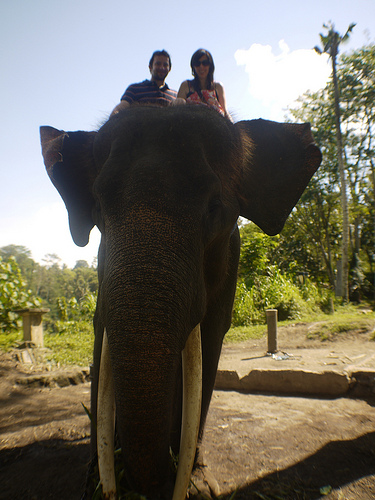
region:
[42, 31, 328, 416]
two people on the back of an elephant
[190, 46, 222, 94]
a woman with long hair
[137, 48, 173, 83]
a man with black hair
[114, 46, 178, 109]
a man wearing a striped shirt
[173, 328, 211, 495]
a long ivory elephant tusk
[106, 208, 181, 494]
the trunk of an elephant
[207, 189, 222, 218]
the eye of an elephant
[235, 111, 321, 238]
the ear of an elephant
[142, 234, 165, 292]
wrinkled skin on an elephant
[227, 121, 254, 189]
hair on an elephant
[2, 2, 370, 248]
blue of daytime sky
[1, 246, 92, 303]
green leaves on trees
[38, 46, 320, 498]
two people on top of elephant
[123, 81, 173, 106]
striped shirt on man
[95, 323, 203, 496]
two white ivory tusks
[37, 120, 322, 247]
two flapping elephant ears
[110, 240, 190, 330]
wrinkles on elephant skin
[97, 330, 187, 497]
vegetation in elephant trunk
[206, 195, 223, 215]
eye on elephant head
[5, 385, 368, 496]
dirt on ground surface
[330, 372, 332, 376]
part of a rock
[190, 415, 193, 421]
part of a trunk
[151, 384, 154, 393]
part of an elephant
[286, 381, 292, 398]
edge of a rock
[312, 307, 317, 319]
part of a stem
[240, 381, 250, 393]
edge of a rock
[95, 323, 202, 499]
two white tusks on the elephant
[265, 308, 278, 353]
a metal pole on top of the ground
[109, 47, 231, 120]
a man and woman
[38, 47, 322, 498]
two people riding an elephant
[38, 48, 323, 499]
a man and woman on top of an elelphant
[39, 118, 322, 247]
the elephant's two ears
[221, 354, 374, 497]
concrete on the ground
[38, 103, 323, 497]
a brown elephant standing on the concrete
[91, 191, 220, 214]
an elephant's two eyes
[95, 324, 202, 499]
tusks on an elephant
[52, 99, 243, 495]
front of large elephant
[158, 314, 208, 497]
white ivory tusk of elephant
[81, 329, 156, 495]
white ivory tusk of elephant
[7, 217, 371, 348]
thick forest growing around area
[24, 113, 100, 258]
right ear of large elephant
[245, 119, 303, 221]
left ear of large elephant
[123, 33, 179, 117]
man riding atop elephant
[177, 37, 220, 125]
woman riding atop elephant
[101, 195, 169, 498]
long trunk of elephant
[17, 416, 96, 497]
shadow of elephant on ground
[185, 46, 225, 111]
woman sitting on the elephant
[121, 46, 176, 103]
man sitting on the elephant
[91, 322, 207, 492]
white tusks on the elephant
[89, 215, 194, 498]
trunk of the elephant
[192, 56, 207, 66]
sunglasses the woman is wearing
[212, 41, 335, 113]
white cloud in the sky